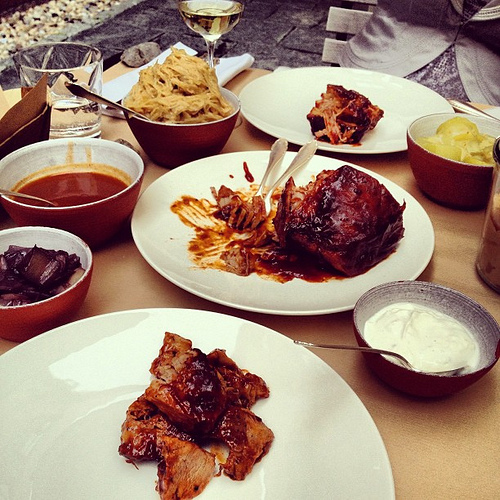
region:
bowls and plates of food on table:
[70, 42, 450, 473]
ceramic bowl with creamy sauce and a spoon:
[345, 260, 490, 395]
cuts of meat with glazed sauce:
[110, 327, 280, 492]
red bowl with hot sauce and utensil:
[2, 125, 142, 235]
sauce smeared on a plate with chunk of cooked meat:
[170, 145, 420, 286]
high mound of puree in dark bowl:
[116, 35, 236, 145]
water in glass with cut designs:
[15, 41, 105, 141]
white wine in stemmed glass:
[172, 2, 247, 82]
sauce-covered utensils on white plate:
[161, 136, 304, 277]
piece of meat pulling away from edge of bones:
[278, 72, 388, 150]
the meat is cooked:
[262, 147, 409, 277]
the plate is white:
[21, 357, 96, 468]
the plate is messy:
[157, 125, 332, 292]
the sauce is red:
[0, 135, 153, 250]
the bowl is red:
[2, 132, 144, 251]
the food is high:
[95, 26, 246, 183]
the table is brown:
[409, 421, 466, 498]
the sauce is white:
[358, 287, 487, 387]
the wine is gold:
[172, 1, 239, 54]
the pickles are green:
[402, 86, 497, 194]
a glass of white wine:
[176, 2, 246, 84]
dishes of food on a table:
[26, 16, 459, 484]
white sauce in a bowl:
[349, 283, 498, 404]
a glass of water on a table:
[13, 27, 142, 149]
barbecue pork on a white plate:
[71, 320, 324, 497]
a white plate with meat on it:
[151, 133, 456, 325]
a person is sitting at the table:
[326, 5, 498, 117]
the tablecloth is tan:
[4, 76, 485, 493]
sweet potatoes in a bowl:
[104, 37, 244, 152]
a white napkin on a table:
[102, 33, 264, 138]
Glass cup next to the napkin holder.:
[18, 38, 108, 138]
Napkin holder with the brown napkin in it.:
[0, 75, 57, 146]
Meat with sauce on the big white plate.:
[122, 318, 280, 498]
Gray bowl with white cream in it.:
[348, 281, 498, 392]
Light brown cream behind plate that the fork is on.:
[127, 50, 231, 120]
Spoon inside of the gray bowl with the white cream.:
[291, 334, 471, 378]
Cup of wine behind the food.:
[175, 2, 244, 103]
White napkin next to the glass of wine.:
[106, 21, 263, 114]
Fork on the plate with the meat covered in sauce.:
[218, 146, 305, 216]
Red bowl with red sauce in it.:
[2, 146, 144, 235]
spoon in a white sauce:
[280, 277, 494, 412]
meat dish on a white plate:
[176, 156, 416, 286]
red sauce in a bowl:
[7, 144, 132, 249]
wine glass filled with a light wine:
[179, 0, 244, 68]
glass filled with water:
[4, 36, 112, 148]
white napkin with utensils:
[88, 50, 260, 142]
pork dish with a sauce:
[95, 327, 308, 499]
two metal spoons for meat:
[223, 130, 322, 226]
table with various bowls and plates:
[1, 44, 498, 489]